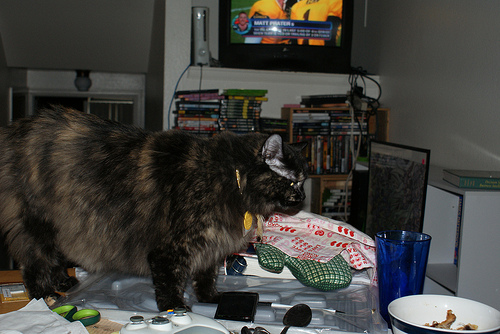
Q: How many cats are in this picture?
A: One.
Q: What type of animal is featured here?
A: Cat.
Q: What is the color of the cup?
A: Blue.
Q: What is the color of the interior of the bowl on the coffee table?
A: White.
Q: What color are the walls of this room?
A: White.